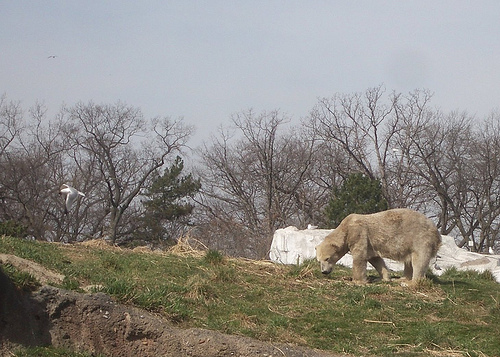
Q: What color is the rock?
A: Grey.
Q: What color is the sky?
A: Light blue.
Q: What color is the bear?
A: White.